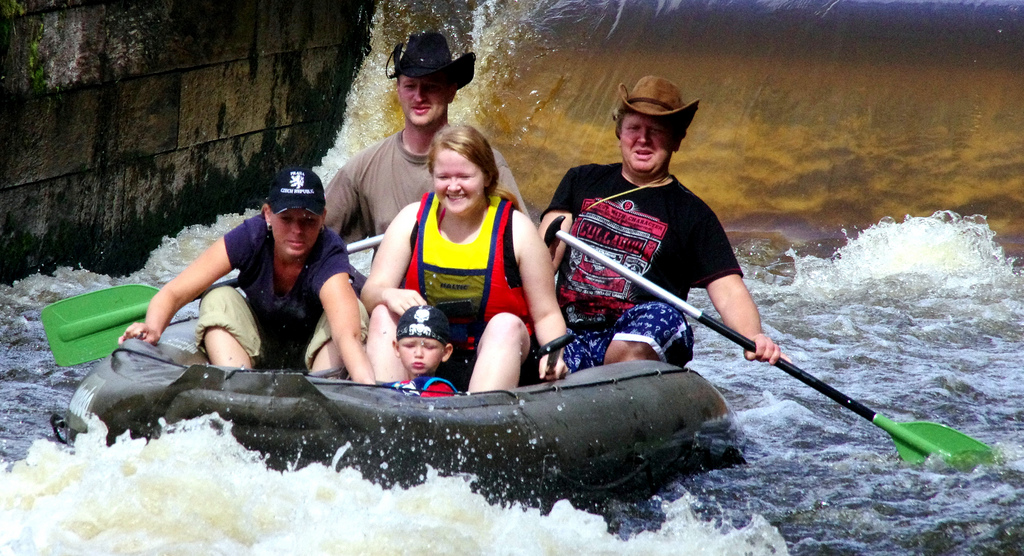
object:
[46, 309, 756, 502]
boat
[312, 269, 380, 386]
arm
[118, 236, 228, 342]
arm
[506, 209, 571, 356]
white arm1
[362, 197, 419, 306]
white arm2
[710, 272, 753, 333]
white arm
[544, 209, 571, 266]
white arm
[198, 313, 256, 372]
white leg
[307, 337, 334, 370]
white leg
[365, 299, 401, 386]
white leg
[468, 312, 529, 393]
white leg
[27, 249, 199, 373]
oar1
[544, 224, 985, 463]
oar2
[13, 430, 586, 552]
wave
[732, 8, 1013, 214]
brown water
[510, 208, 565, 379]
arm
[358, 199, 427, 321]
arm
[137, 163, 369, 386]
person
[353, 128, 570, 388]
person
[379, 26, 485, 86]
cowboy hat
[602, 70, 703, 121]
cowboy hat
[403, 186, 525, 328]
flotation vest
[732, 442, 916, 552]
water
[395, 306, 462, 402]
child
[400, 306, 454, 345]
cap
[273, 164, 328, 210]
cap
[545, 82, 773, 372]
man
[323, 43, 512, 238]
man